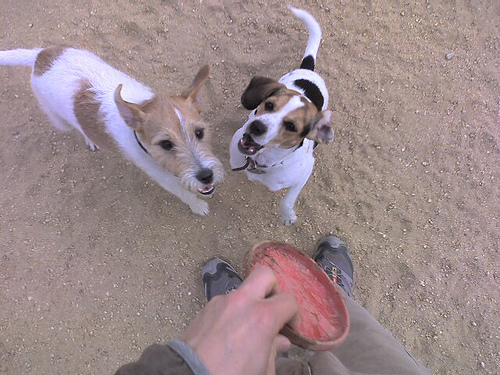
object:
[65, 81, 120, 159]
spot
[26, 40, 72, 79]
spot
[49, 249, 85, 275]
pebbles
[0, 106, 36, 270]
dirt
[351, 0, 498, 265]
brown dirt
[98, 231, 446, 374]
man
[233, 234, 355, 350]
disc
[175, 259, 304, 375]
hand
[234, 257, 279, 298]
finger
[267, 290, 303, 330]
finger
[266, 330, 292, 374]
finger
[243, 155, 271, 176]
collar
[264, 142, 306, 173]
neck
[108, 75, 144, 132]
ear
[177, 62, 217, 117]
ear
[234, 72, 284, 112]
ear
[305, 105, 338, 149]
ear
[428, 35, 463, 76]
pebbles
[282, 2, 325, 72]
tail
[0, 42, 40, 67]
tail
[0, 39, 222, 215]
dog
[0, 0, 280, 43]
dirt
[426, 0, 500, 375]
ground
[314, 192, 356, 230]
dirt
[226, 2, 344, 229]
dog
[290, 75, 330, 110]
spots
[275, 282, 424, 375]
pants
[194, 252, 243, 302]
shoe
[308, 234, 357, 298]
shoe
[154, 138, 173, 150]
eye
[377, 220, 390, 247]
pebbles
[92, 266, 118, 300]
pebbles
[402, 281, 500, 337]
dirt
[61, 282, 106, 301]
pebbles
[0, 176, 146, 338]
dirt